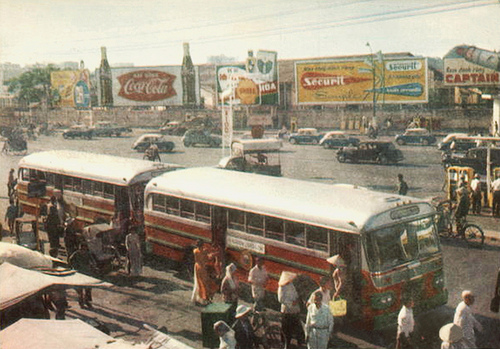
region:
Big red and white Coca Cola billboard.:
[92, 39, 201, 106]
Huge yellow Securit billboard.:
[293, 56, 428, 111]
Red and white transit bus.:
[142, 169, 445, 319]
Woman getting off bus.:
[327, 249, 352, 309]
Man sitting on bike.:
[433, 185, 484, 246]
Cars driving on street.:
[289, 126, 435, 171]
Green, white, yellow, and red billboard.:
[215, 49, 281, 106]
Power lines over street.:
[24, 0, 499, 55]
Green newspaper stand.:
[197, 300, 234, 344]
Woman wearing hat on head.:
[326, 252, 351, 326]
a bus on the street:
[146, 157, 456, 314]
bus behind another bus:
[8, 143, 151, 250]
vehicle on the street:
[338, 138, 402, 165]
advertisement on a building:
[95, 42, 206, 108]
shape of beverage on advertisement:
[90, 45, 120, 108]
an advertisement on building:
[298, 57, 425, 109]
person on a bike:
[441, 181, 487, 246]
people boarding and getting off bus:
[158, 236, 351, 308]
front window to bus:
[373, 233, 442, 253]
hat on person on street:
[276, 269, 301, 286]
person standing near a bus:
[185, 235, 218, 310]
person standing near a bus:
[120, 217, 147, 280]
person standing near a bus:
[215, 255, 242, 306]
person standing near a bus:
[245, 252, 275, 319]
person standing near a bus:
[274, 263, 308, 347]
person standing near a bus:
[322, 249, 353, 304]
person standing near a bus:
[301, 285, 339, 347]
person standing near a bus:
[389, 289, 426, 347]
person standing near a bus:
[437, 318, 467, 347]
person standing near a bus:
[449, 286, 489, 347]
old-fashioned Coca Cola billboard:
[90, 40, 210, 112]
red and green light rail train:
[12, 142, 454, 336]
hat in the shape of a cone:
[274, 266, 299, 289]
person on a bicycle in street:
[435, 182, 487, 249]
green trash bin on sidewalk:
[197, 296, 232, 347]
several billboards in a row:
[30, 41, 497, 110]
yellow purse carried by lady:
[326, 289, 348, 319]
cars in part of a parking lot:
[281, 118, 466, 160]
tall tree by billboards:
[3, 62, 56, 110]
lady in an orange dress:
[185, 234, 215, 308]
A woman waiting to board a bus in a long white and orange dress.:
[188, 238, 215, 305]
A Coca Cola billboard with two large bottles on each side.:
[89, 42, 201, 109]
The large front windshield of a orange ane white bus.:
[361, 215, 442, 272]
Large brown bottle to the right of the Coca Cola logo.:
[180, 41, 198, 103]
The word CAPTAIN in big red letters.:
[444, 69, 497, 84]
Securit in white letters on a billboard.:
[303, 72, 346, 87]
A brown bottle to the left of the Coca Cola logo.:
[97, 45, 115, 105]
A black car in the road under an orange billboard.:
[335, 135, 406, 166]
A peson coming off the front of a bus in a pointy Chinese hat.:
[326, 253, 350, 300]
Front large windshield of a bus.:
[365, 217, 440, 270]